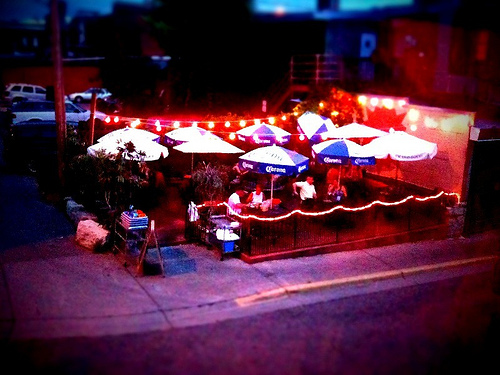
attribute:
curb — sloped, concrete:
[0, 207, 496, 341]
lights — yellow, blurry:
[358, 95, 475, 135]